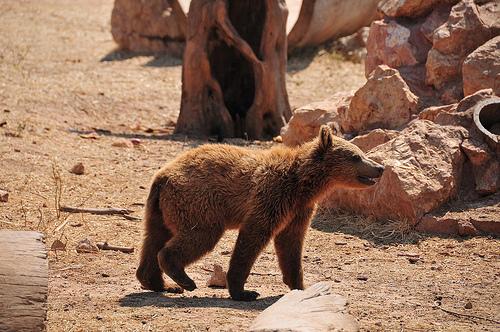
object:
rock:
[309, 112, 464, 221]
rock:
[462, 34, 499, 103]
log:
[0, 228, 52, 331]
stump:
[175, 0, 292, 139]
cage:
[0, 1, 499, 331]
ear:
[324, 120, 340, 138]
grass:
[303, 207, 499, 331]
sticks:
[433, 299, 500, 325]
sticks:
[61, 204, 134, 215]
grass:
[0, 0, 134, 331]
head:
[318, 120, 386, 190]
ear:
[317, 124, 333, 148]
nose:
[376, 165, 385, 174]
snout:
[367, 162, 385, 178]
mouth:
[356, 175, 383, 187]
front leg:
[226, 211, 291, 290]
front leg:
[273, 211, 313, 289]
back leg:
[137, 197, 174, 287]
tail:
[146, 173, 167, 203]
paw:
[231, 290, 260, 299]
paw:
[171, 277, 198, 291]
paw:
[164, 282, 184, 293]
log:
[247, 280, 362, 331]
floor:
[0, 0, 499, 330]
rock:
[66, 158, 94, 178]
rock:
[50, 234, 69, 248]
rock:
[0, 117, 10, 127]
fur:
[191, 152, 257, 196]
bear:
[135, 121, 387, 301]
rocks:
[325, 117, 470, 225]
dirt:
[0, 0, 499, 331]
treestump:
[173, 0, 293, 140]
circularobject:
[473, 97, 499, 143]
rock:
[336, 64, 419, 133]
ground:
[0, 0, 499, 330]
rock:
[370, 12, 475, 94]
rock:
[372, 12, 475, 151]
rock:
[389, 1, 479, 124]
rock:
[394, 70, 469, 205]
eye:
[347, 155, 361, 162]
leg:
[157, 209, 224, 279]